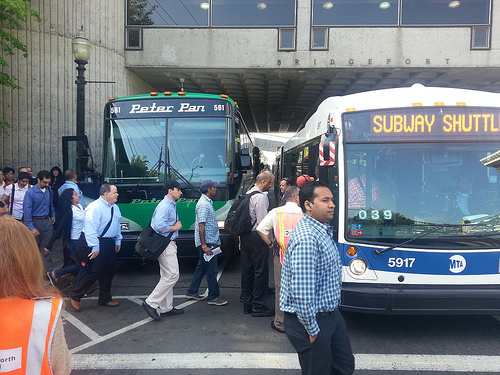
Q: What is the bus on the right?
A: Subway shuttle.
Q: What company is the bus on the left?
A: Peter Pan.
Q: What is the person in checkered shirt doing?
A: Crossing the street.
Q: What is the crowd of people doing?
A: Getting on bus.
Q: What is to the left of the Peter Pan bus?
A: Lamppole.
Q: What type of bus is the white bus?
A: A subway shuttle.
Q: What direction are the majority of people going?
A: To the right.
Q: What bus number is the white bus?
A: 5917.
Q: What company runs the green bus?
A: Peter Pan.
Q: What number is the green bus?
A: 581.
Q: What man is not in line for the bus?
A: The man with the checkered shirt.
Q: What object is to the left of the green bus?
A: A street lamp.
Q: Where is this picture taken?
A: A bus stop.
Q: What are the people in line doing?
A: Boarding the bus.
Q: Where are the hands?
A: In the man pockets.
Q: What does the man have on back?
A: A backpack.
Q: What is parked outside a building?
A: A green and black bus.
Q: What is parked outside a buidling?
A: A white and blue bus.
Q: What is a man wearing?
A: Blue long sleeve plaid shirt.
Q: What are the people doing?
A: Getting off and on buses.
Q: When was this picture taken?
A: Daytime.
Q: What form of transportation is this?
A: Bus.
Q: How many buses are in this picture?
A: 2.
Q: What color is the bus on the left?
A: Green.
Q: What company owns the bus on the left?
A: Peter Pan.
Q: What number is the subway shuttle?
A: 5917.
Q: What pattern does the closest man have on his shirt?
A: Checkerboard.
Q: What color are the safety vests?
A: Orange.